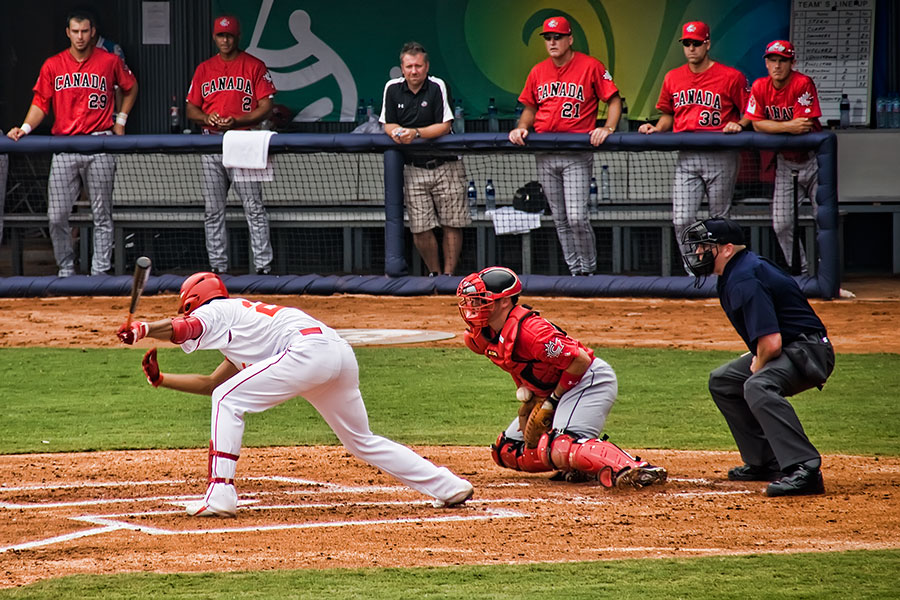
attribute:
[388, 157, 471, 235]
shorts — khaki 